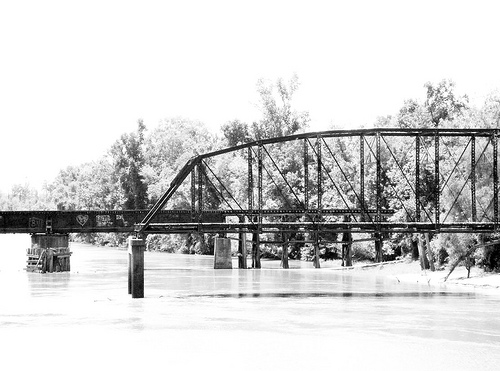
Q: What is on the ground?
A: Snow.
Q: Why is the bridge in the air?
A: So people can cross safely.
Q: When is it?
A: Day time.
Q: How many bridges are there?
A: One.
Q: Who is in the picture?
A: No one.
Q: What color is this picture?
A: Black and white.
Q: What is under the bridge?
A: Water.